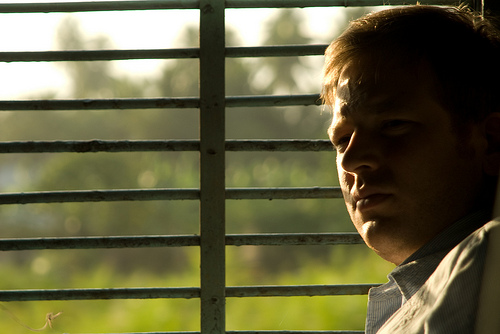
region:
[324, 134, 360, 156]
eye of a person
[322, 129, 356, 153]
right eye of a person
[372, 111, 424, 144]
left eye of a person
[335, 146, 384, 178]
nose of a person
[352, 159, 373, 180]
nostril of a person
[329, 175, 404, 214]
mouth of a person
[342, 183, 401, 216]
lips of a person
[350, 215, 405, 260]
chin of a person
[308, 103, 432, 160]
eyes of a person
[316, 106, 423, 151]
pair of eyes on a person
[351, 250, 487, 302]
man wearing a dress shirt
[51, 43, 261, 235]
trees on a leaves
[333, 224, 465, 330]
man wearing a dress shirt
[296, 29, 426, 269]
man sitting in front of a window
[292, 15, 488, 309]
man sitting in front of a window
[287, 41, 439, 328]
man sitting in front of a window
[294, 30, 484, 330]
man sitting in front of a window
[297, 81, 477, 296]
man is staring in the open air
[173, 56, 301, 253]
the fence is made of metals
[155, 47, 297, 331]
the fence is rusted grey in color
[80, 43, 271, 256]
plants are seen through the fence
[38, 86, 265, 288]
plants are green in color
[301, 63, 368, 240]
light reflected on mans head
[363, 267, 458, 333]
the shirt is colorles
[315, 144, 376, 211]
the person is light skinned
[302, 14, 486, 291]
A man sad face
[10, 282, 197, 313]
A metalic window pole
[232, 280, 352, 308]
A metalic window pole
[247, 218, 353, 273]
A metalic window pole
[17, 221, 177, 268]
A metalic window pole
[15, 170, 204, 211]
A metalic window pole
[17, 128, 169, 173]
A metalic window pole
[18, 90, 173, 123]
A metalic window pole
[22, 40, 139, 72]
A metalic window pole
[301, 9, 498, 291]
a man sitting next to a window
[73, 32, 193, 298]
metal bars on a window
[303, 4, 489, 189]
a man with blonde hair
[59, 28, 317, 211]
a group of trees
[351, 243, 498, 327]
a person wearing a collared shirt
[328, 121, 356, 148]
the eye of a person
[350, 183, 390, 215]
the mouth of a person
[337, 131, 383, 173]
the nose of a person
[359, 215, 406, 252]
the chin of a person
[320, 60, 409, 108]
the forehead of a person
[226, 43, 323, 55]
wooden slat on window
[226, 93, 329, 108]
wooden slat on window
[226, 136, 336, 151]
wooden slat on window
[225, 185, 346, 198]
wooden slat on window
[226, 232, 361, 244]
wooden slat on window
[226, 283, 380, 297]
wooden slat on window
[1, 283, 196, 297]
wooden slat on window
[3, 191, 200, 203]
wooden slat on window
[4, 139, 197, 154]
wooden slat on window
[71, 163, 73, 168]
A green leaf on a plant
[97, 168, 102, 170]
A green leaf on a plant